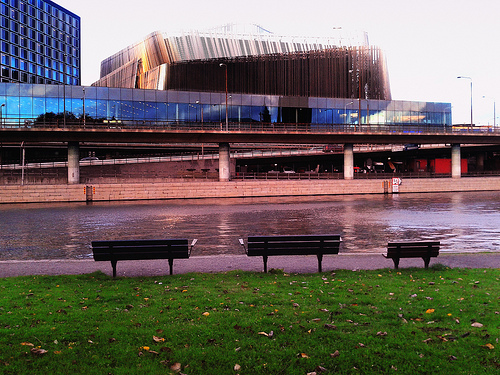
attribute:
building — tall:
[0, 0, 87, 87]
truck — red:
[405, 139, 464, 175]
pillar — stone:
[65, 147, 77, 185]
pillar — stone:
[217, 143, 229, 180]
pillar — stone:
[343, 142, 352, 177]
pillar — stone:
[450, 142, 459, 177]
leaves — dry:
[137, 304, 233, 359]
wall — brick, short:
[1, 177, 498, 204]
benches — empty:
[91, 233, 440, 275]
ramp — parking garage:
[3, 144, 435, 176]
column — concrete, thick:
[218, 143, 230, 180]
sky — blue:
[1, 0, 498, 135]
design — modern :
[105, 22, 421, 133]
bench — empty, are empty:
[91, 239, 189, 277]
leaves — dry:
[389, 299, 468, 370]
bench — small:
[379, 236, 444, 266]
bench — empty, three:
[242, 232, 340, 270]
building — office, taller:
[28, 11, 457, 210]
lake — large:
[3, 200, 498, 268]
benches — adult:
[88, 232, 458, 278]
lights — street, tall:
[446, 56, 485, 127]